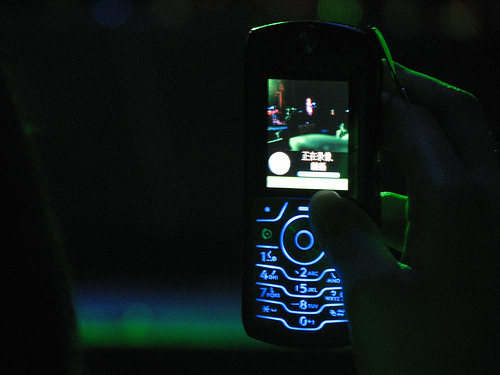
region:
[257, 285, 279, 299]
a number on the cell phone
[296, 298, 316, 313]
a number on the cell phone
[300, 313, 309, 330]
a number on the cell phone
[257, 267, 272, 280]
a number on the cell phone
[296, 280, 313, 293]
a number on the cell phone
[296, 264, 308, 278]
a number on the cell phone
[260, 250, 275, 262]
a number on the cell phone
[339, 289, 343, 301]
a number on the cell phone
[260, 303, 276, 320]
a button on the cellphone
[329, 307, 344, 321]
a button on the cell phone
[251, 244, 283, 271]
button on a cellphone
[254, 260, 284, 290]
button on a cellphone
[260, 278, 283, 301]
button on a cellphone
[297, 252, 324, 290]
button on a cellphone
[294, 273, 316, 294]
button on a cellphone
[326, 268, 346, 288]
button on a cellphone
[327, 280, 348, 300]
button on a cellphone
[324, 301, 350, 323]
button on a cellphone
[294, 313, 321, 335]
button on a cellphone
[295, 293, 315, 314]
button on a cellphone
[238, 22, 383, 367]
CELLPHONE IN PERSON'S HAND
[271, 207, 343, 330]
BLUE LIGHT BEHIND KEYS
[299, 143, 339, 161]
ASIAN WRITING ON PHONE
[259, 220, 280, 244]
GREEN ON BUTTON ON PHONE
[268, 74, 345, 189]
ILLUMINATED SCREEN OF PHONE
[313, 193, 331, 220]
FINGER NAIL OF HAND HOLDING PHONE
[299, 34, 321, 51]
SMALL LOGO ON PHONE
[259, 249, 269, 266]
NUMBER 1 ON KEYPAD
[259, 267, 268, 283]
NUMBER 4 ON KEYPAD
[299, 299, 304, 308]
NUMBER 8 ON KEYPAD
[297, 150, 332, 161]
Asian text on the screen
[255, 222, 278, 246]
green call button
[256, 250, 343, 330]
glowing blue numbers on the phone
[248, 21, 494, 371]
a person holding a phone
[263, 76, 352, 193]
phone screen is on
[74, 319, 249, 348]
a green stripe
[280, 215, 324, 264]
round button the phone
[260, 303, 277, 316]
star key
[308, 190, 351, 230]
no nail polish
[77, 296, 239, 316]
blue stripe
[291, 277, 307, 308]
part of a clock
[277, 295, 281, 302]
edge of a phone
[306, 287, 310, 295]
part of a button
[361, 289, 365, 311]
edge of a finger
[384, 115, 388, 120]
edge of a phone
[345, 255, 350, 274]
part of a finger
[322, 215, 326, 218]
part of a finger